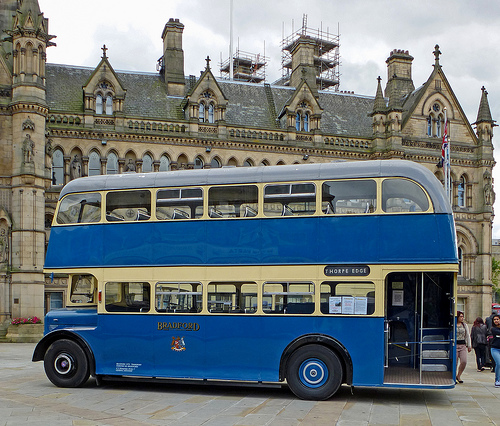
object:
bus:
[31, 159, 460, 400]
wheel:
[282, 343, 342, 401]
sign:
[322, 265, 367, 275]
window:
[317, 281, 377, 318]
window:
[318, 178, 378, 217]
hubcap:
[297, 357, 329, 389]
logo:
[167, 335, 187, 353]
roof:
[56, 156, 454, 206]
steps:
[417, 326, 454, 372]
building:
[1, 0, 496, 349]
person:
[455, 310, 474, 385]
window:
[55, 191, 101, 223]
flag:
[435, 119, 451, 171]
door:
[385, 272, 457, 388]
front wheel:
[44, 336, 91, 388]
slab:
[397, 412, 431, 425]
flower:
[9, 312, 42, 326]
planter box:
[2, 322, 48, 343]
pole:
[440, 106, 452, 206]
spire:
[0, 0, 57, 48]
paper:
[353, 294, 367, 314]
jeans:
[487, 347, 499, 383]